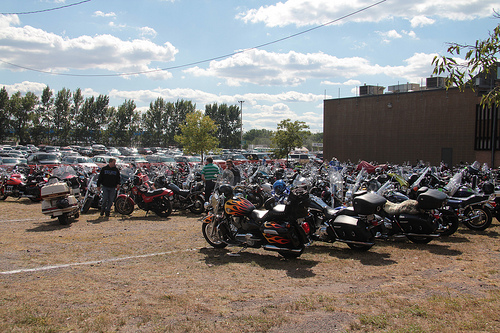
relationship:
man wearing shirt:
[198, 152, 225, 202] [203, 165, 214, 180]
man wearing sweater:
[87, 151, 127, 223] [89, 158, 124, 218]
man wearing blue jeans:
[87, 151, 127, 221] [93, 185, 120, 222]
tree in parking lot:
[177, 112, 220, 154] [3, 136, 484, 330]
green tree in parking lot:
[274, 117, 306, 147] [3, 136, 484, 330]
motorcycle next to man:
[115, 165, 179, 227] [89, 154, 125, 222]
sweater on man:
[89, 159, 125, 195] [89, 154, 125, 222]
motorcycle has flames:
[203, 187, 300, 258] [226, 200, 248, 212]